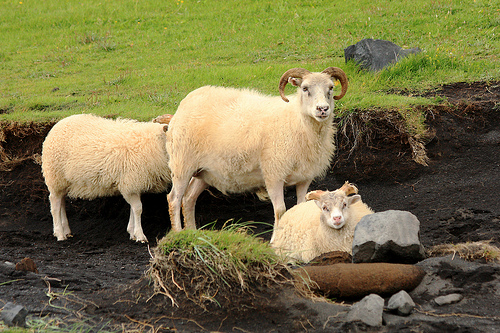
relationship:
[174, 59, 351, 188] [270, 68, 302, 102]
sheep has horn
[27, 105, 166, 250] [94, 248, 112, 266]
sheep in mud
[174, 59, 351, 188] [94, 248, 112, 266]
sheep in mud